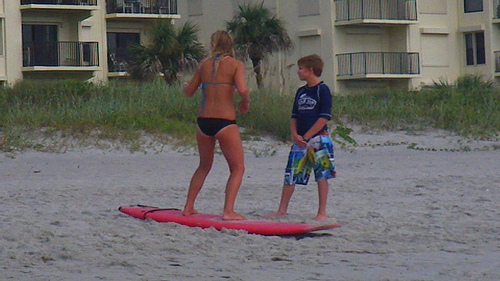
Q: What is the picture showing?
A: It is showing a beach.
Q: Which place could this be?
A: It is a beach.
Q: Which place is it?
A: It is a beach.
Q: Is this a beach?
A: Yes, it is a beach.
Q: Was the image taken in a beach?
A: Yes, it was taken in a beach.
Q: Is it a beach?
A: Yes, it is a beach.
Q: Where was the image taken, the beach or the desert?
A: It was taken at the beach.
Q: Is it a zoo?
A: No, it is a beach.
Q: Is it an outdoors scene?
A: Yes, it is outdoors.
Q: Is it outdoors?
A: Yes, it is outdoors.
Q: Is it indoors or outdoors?
A: It is outdoors.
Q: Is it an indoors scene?
A: No, it is outdoors.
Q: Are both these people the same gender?
A: No, they are both male and female.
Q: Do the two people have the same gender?
A: No, they are both male and female.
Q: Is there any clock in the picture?
A: No, there are no clocks.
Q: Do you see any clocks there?
A: No, there are no clocks.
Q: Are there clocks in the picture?
A: No, there are no clocks.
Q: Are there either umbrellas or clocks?
A: No, there are no clocks or umbrellas.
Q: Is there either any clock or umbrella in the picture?
A: No, there are no clocks or umbrellas.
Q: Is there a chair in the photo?
A: Yes, there is a chair.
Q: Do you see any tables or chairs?
A: Yes, there is a chair.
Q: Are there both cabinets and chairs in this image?
A: No, there is a chair but no cabinets.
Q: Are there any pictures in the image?
A: No, there are no pictures.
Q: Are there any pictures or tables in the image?
A: No, there are no pictures or tables.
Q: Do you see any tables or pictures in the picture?
A: No, there are no pictures or tables.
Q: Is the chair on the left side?
A: Yes, the chair is on the left of the image.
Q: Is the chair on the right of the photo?
A: No, the chair is on the left of the image.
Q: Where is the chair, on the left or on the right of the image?
A: The chair is on the left of the image.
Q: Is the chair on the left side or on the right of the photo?
A: The chair is on the left of the image.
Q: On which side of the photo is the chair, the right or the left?
A: The chair is on the left of the image.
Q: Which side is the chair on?
A: The chair is on the left of the image.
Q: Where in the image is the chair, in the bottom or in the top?
A: The chair is in the top of the image.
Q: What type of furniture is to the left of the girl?
A: The piece of furniture is a chair.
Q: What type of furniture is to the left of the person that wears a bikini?
A: The piece of furniture is a chair.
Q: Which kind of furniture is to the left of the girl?
A: The piece of furniture is a chair.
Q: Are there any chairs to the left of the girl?
A: Yes, there is a chair to the left of the girl.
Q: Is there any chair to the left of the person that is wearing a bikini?
A: Yes, there is a chair to the left of the girl.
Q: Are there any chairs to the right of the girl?
A: No, the chair is to the left of the girl.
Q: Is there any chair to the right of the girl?
A: No, the chair is to the left of the girl.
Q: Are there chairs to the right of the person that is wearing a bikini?
A: No, the chair is to the left of the girl.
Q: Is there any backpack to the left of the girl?
A: No, there is a chair to the left of the girl.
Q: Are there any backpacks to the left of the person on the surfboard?
A: No, there is a chair to the left of the girl.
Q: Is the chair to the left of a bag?
A: No, the chair is to the left of the girl.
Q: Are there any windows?
A: Yes, there is a window.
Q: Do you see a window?
A: Yes, there is a window.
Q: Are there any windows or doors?
A: Yes, there is a window.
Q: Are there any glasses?
A: No, there are no glasses.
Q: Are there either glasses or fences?
A: No, there are no glasses or fences.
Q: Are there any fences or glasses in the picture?
A: No, there are no glasses or fences.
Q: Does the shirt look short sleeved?
A: Yes, the shirt is short sleeved.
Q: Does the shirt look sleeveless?
A: No, the shirt is short sleeved.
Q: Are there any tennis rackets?
A: No, there are no tennis rackets.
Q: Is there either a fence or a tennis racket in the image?
A: No, there are no rackets or fences.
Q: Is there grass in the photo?
A: Yes, there is grass.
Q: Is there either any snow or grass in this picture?
A: Yes, there is grass.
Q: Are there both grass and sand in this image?
A: Yes, there are both grass and sand.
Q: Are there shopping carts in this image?
A: No, there are no shopping carts.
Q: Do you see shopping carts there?
A: No, there are no shopping carts.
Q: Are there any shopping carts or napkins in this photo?
A: No, there are no shopping carts or napkins.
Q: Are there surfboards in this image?
A: Yes, there is a surfboard.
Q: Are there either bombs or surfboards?
A: Yes, there is a surfboard.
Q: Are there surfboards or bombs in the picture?
A: Yes, there is a surfboard.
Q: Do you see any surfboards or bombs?
A: Yes, there is a surfboard.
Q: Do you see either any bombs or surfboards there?
A: Yes, there is a surfboard.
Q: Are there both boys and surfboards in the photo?
A: Yes, there are both a surfboard and a boy.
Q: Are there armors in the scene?
A: No, there are no armors.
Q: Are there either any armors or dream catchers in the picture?
A: No, there are no armors or dream catchers.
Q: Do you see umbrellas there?
A: No, there are no umbrellas.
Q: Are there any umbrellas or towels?
A: No, there are no umbrellas or towels.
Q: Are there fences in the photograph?
A: No, there are no fences.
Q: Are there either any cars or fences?
A: No, there are no fences or cars.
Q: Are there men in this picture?
A: No, there are no men.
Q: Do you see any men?
A: No, there are no men.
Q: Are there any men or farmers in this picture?
A: No, there are no men or farmers.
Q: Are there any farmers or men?
A: No, there are no men or farmers.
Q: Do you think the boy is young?
A: Yes, the boy is young.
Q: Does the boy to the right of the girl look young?
A: Yes, the boy is young.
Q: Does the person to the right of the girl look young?
A: Yes, the boy is young.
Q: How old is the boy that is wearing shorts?
A: The boy is young.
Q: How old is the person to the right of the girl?
A: The boy is young.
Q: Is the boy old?
A: No, the boy is young.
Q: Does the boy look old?
A: No, the boy is young.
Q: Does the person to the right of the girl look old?
A: No, the boy is young.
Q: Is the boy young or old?
A: The boy is young.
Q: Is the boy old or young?
A: The boy is young.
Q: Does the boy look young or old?
A: The boy is young.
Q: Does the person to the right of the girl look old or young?
A: The boy is young.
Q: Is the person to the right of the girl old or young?
A: The boy is young.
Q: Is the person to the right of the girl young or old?
A: The boy is young.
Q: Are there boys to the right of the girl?
A: Yes, there is a boy to the right of the girl.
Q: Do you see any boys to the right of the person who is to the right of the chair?
A: Yes, there is a boy to the right of the girl.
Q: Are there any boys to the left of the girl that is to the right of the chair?
A: No, the boy is to the right of the girl.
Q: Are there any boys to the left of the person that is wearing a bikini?
A: No, the boy is to the right of the girl.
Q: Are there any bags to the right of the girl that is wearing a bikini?
A: No, there is a boy to the right of the girl.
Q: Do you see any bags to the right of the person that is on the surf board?
A: No, there is a boy to the right of the girl.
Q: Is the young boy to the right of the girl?
A: Yes, the boy is to the right of the girl.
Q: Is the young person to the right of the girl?
A: Yes, the boy is to the right of the girl.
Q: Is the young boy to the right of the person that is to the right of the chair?
A: Yes, the boy is to the right of the girl.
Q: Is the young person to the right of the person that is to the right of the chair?
A: Yes, the boy is to the right of the girl.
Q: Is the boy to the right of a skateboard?
A: No, the boy is to the right of the girl.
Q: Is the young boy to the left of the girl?
A: No, the boy is to the right of the girl.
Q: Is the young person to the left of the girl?
A: No, the boy is to the right of the girl.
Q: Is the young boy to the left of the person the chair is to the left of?
A: No, the boy is to the right of the girl.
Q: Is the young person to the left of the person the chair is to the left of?
A: No, the boy is to the right of the girl.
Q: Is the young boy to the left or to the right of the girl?
A: The boy is to the right of the girl.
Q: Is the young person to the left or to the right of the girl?
A: The boy is to the right of the girl.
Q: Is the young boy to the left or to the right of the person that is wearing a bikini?
A: The boy is to the right of the girl.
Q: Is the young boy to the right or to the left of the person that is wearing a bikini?
A: The boy is to the right of the girl.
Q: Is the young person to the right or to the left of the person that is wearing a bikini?
A: The boy is to the right of the girl.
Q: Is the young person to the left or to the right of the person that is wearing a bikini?
A: The boy is to the right of the girl.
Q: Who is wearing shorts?
A: The boy is wearing shorts.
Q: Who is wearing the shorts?
A: The boy is wearing shorts.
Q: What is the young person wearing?
A: The boy is wearing shorts.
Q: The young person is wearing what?
A: The boy is wearing shorts.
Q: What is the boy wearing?
A: The boy is wearing shorts.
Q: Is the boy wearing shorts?
A: Yes, the boy is wearing shorts.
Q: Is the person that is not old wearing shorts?
A: Yes, the boy is wearing shorts.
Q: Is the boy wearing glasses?
A: No, the boy is wearing shorts.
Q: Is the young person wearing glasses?
A: No, the boy is wearing shorts.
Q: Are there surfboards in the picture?
A: Yes, there is a surfboard.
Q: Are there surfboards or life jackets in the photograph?
A: Yes, there is a surfboard.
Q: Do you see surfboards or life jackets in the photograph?
A: Yes, there is a surfboard.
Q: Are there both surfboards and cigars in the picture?
A: No, there is a surfboard but no cigars.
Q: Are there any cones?
A: No, there are no cones.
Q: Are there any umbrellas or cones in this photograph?
A: No, there are no cones or umbrellas.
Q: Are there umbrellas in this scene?
A: No, there are no umbrellas.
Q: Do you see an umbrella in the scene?
A: No, there are no umbrellas.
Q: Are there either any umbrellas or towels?
A: No, there are no umbrellas or towels.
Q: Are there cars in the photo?
A: No, there are no cars.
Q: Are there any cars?
A: No, there are no cars.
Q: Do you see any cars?
A: No, there are no cars.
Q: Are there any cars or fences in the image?
A: No, there are no cars or fences.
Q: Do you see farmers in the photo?
A: No, there are no farmers.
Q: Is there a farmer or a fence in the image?
A: No, there are no farmers or fences.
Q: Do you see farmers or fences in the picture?
A: No, there are no farmers or fences.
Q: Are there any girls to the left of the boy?
A: Yes, there is a girl to the left of the boy.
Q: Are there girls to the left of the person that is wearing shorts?
A: Yes, there is a girl to the left of the boy.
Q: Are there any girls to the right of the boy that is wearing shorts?
A: No, the girl is to the left of the boy.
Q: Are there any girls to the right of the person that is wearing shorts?
A: No, the girl is to the left of the boy.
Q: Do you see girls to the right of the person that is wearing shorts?
A: No, the girl is to the left of the boy.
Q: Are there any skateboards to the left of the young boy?
A: No, there is a girl to the left of the boy.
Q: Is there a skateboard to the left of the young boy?
A: No, there is a girl to the left of the boy.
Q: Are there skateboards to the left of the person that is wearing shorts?
A: No, there is a girl to the left of the boy.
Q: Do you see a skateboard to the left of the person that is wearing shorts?
A: No, there is a girl to the left of the boy.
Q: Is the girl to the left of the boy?
A: Yes, the girl is to the left of the boy.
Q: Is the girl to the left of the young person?
A: Yes, the girl is to the left of the boy.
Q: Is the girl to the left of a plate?
A: No, the girl is to the left of the boy.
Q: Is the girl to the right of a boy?
A: No, the girl is to the left of a boy.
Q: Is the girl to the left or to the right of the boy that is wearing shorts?
A: The girl is to the left of the boy.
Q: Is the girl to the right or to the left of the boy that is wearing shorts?
A: The girl is to the left of the boy.